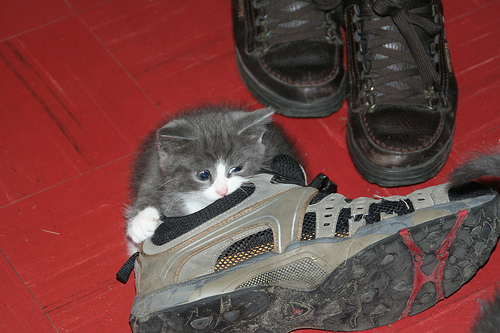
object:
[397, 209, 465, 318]
x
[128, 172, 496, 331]
shoe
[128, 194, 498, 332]
sole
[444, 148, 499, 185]
tail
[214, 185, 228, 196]
nose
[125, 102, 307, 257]
kitten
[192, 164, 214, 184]
eye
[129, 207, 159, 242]
paw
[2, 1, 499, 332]
tile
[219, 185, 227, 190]
fur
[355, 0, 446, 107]
lace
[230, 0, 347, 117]
show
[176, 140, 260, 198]
face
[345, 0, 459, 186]
shoe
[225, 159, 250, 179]
eye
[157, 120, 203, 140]
ear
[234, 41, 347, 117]
sole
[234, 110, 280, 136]
ear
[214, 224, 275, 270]
mesh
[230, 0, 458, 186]
pair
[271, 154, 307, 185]
tongue